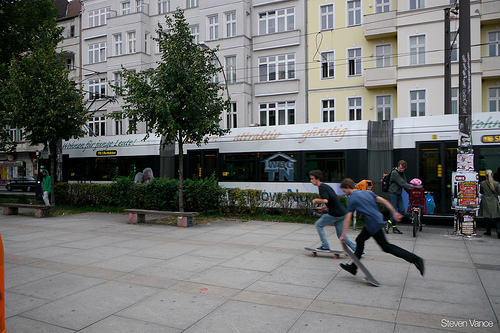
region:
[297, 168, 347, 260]
a skateboarder in a black shirt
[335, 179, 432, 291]
a skateboarding doing a trick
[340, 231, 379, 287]
a tilted black skateboard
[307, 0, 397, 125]
a tall yellow building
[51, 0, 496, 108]
a row of buildings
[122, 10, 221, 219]
a small planted tree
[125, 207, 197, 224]
a small park bench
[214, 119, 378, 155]
a white canopy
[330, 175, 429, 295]
a skateboarder in a blue shirt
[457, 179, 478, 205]
a red sign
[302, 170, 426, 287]
two young men skateboarding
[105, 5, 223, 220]
green leaves on tree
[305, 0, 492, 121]
yellow and tan building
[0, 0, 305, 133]
gray building with windows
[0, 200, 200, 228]
two parking benches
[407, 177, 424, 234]
child sitting in bicycle seat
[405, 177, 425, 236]
child wearing pink helmet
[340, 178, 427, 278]
skater wearing black pants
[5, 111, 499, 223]
white city train with black windows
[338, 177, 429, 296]
A man about to skateboard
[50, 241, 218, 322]
Concrete tile design on the ground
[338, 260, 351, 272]
A man's black shoe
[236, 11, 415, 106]
Buildings in the background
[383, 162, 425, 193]
A person in the background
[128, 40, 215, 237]
A tree behind a bench area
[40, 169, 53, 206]
A person in the background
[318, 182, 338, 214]
A black shirt on a person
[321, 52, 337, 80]
Window of a building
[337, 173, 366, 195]
head of a person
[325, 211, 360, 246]
arm of a person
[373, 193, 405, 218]
arm of a person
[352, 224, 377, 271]
leg of a person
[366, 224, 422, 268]
leg of a person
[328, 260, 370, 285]
feet of a person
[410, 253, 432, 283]
feet of a person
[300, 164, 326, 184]
head of a person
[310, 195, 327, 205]
arm of a person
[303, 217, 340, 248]
leg of a person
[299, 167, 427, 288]
Two skateboarders on sidewalk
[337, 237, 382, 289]
Hand holding black skateboard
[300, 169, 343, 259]
Boy with one foot on skateboard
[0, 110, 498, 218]
Train arriving at station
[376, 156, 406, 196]
Man with grey jacket and backpack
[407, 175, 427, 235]
Child with pink bike helmet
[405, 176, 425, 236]
Child sitting on bike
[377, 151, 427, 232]
Man holding up bike with child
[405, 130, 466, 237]
Bicyclist waiting to board train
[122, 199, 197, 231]
Park bench in front of tree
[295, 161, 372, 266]
A guy is skateboarding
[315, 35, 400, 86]
Three windows on a building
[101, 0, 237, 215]
Green leaves on a small tree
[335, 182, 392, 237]
A blue short sleeved shirt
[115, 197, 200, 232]
A bench is sitting empty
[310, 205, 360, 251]
A pair of blue jeans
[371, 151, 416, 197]
A man is carrying a backpack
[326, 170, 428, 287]
A guy holding a skateboard is running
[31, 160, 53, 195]
Person is wearing green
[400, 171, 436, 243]
A kid riding a bicycle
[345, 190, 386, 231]
blue short sleeve shirt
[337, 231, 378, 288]
hand holding black skateboard